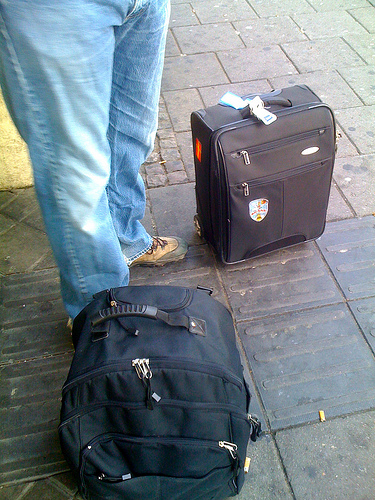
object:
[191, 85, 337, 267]
suitcase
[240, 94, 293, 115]
handle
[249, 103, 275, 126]
tag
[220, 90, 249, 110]
tag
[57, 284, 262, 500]
bag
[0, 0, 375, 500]
ground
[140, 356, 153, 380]
zipper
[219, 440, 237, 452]
zipper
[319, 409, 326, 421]
cigarette butt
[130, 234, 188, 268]
shoe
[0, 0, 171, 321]
jeans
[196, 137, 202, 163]
patch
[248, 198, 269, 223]
patch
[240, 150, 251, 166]
zipper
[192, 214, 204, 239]
wheel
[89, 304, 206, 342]
handle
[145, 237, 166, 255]
lace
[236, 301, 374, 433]
tile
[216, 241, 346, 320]
tile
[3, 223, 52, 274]
tile